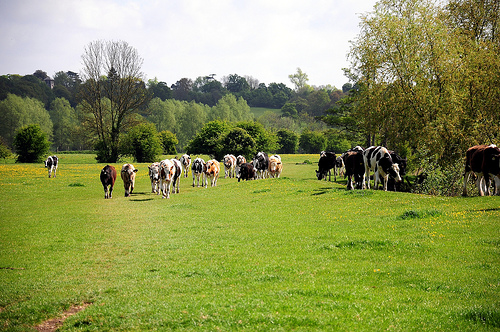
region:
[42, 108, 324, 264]
This is a bunch of animals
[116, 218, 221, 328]
This is a field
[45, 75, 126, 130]
This is an old tree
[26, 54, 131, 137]
The tree has no leaves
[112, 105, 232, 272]
These are a bunch of cows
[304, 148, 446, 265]
The cows are eating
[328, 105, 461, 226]
This cow is black and white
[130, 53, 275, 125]
These are pine trees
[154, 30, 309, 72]
The sky is very cloudy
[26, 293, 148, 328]
This is a patch of dirt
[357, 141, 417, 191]
cow in a field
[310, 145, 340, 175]
cow in a field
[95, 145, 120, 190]
cow in a field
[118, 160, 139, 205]
cow in a field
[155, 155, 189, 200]
cow in a field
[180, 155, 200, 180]
cow in a field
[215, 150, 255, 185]
cow in a field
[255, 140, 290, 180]
cow in a field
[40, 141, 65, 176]
cow in a field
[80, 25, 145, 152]
tree in a field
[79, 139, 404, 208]
group of cattle on a field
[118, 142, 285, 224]
group of cows walking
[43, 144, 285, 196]
group of cows walking forward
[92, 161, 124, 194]
brown cow walking forward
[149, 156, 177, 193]
two white cows walking forwrad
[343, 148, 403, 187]
black and white cow walking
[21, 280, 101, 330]
brown dirt in grass field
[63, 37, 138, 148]
tall tree with no leaves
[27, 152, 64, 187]
cow walking by itself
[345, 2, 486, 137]
large tree covered in green leaves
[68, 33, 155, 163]
Tree without leaves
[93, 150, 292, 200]
Group of cows walking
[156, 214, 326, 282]
short, green grass in a pasture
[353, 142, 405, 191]
Black and white cow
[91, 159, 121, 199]
Brown cow walking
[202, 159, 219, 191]
Tan and white colored cow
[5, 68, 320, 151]
Trees on a distant hillside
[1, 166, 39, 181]
Yellow flowers in pasture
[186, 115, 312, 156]
Bushy, short trees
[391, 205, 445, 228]
Dark green area of grass in pasture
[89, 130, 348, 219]
many cows on field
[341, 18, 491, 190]
green trees behind cows to right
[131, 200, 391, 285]
green grass in front of cows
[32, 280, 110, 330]
brown bare patch in grass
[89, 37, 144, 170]
bare tree behind cows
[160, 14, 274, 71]
sky is grey and cloudy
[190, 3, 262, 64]
puffy clouds in sky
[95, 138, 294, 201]
cows are walking forward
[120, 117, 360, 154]
green bushes in background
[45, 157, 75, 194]
one cow away from others on left